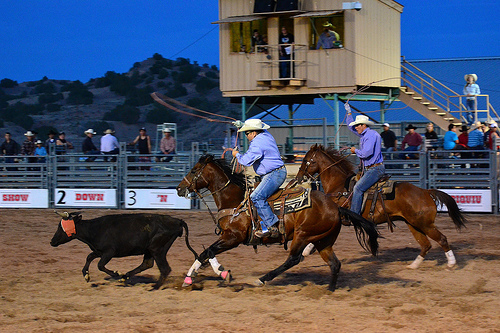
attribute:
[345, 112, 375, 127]
hat — cowboy, white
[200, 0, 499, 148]
trailer — brown, small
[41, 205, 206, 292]
calf — small, being lassoed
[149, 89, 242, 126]
lasso — brown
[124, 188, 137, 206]
number 3 — black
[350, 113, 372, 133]
hat — white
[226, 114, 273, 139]
hat — white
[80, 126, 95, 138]
hat — white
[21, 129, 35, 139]
hat — white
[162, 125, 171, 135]
hat — white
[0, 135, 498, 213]
gray fencing — metal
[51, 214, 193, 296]
bull — young, black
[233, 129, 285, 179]
shirt — blue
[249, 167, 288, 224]
pants — blue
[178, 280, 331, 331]
dirt — brown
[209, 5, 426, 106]
annoucer stand — announcer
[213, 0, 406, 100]
building — large, beige, metal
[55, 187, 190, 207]
sign — long, white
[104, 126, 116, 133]
hat — tan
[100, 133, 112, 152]
shirt — light blue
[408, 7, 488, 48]
sky — blue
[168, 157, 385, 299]
horse — large, brown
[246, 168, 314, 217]
saddle — brown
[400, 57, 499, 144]
staircase — brown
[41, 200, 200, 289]
black bull — running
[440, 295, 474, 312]
footprint — many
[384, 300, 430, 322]
footprint — many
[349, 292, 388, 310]
footprint — many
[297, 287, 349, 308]
footprint — many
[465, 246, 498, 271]
footprint — many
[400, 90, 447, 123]
stairs — light brown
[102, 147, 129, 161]
pants —  black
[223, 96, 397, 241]
outfits — matching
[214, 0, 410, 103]
box — viewing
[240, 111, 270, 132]
hat — white